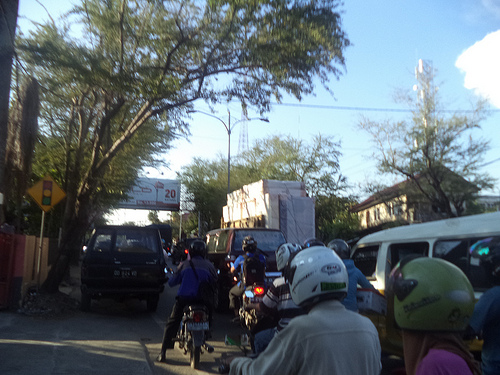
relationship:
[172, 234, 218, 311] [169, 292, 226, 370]
person on a motorcycle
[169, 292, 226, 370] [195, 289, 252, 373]
motorcycle on a street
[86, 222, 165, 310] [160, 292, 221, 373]
vehicle parked at curb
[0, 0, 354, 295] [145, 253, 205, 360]
tree by road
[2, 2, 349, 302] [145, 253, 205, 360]
tree by road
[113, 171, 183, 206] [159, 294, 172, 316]
billboard over street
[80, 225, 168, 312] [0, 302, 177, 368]
vehicle on sidewalk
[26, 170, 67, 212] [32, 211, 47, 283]
sign on pole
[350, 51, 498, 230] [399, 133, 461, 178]
tree has branches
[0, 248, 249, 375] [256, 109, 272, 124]
road has lamp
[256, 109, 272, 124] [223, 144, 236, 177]
lamp on pole